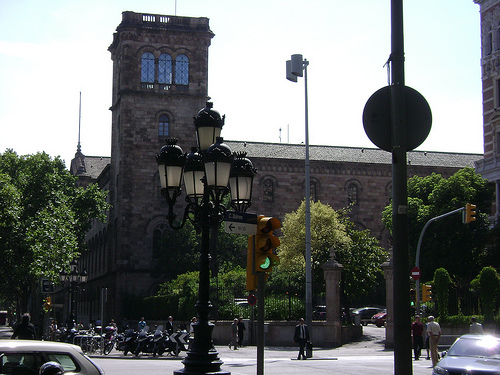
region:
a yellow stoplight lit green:
[242, 212, 283, 303]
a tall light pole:
[282, 50, 319, 363]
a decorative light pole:
[151, 93, 259, 373]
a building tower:
[97, 7, 221, 322]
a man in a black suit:
[284, 314, 315, 364]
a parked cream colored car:
[0, 337, 105, 373]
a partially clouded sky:
[3, 7, 471, 141]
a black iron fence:
[129, 283, 359, 334]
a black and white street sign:
[219, 205, 259, 240]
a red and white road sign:
[404, 250, 430, 285]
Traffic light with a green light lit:
[238, 210, 287, 322]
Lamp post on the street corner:
[149, 97, 263, 362]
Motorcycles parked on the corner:
[110, 312, 191, 362]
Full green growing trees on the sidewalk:
[286, 160, 491, 298]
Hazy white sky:
[221, 10, 476, 126]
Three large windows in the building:
[128, 37, 197, 89]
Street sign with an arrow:
[217, 204, 269, 236]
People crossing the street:
[405, 303, 448, 368]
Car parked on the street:
[430, 315, 498, 370]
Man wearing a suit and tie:
[287, 310, 308, 355]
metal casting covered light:
[156, 135, 183, 195]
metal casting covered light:
[182, 152, 209, 194]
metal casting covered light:
[202, 137, 232, 189]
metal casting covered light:
[228, 155, 252, 212]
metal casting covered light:
[192, 95, 221, 154]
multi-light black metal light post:
[155, 102, 253, 374]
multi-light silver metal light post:
[282, 51, 321, 358]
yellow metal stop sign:
[254, 212, 279, 273]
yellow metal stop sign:
[421, 282, 433, 309]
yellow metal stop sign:
[461, 201, 478, 224]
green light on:
[257, 254, 282, 271]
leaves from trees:
[5, 154, 68, 267]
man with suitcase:
[293, 319, 313, 363]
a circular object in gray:
[362, 87, 434, 154]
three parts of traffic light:
[250, 213, 273, 287]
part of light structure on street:
[155, 132, 184, 219]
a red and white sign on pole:
[407, 268, 419, 283]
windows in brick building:
[132, 47, 202, 94]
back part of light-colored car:
[0, 340, 102, 373]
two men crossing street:
[412, 313, 439, 365]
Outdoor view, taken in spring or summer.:
[5, 11, 482, 367]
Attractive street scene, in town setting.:
[15, 7, 499, 371]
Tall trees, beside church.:
[7, 153, 87, 275]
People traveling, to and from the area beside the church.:
[19, 311, 189, 354]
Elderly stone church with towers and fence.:
[77, 3, 492, 343]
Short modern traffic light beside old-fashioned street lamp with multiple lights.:
[167, 90, 277, 371]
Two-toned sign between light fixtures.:
[221, 211, 261, 239]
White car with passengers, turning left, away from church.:
[1, 340, 113, 372]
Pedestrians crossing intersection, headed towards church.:
[410, 302, 478, 355]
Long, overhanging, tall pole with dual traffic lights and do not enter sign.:
[413, 195, 480, 365]